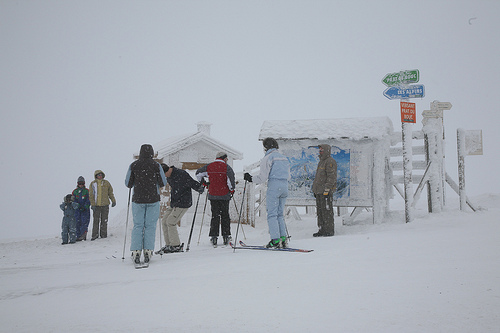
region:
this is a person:
[44, 183, 77, 242]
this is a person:
[61, 172, 101, 248]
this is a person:
[76, 156, 128, 243]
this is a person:
[116, 144, 176, 279]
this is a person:
[153, 152, 200, 269]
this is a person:
[196, 138, 243, 231]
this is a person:
[249, 141, 296, 250]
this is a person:
[306, 137, 358, 254]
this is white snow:
[235, 278, 295, 330]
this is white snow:
[286, 261, 341, 324]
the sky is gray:
[2, 0, 495, 85]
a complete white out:
[1, 2, 498, 327]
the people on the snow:
[88, 129, 378, 276]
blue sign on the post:
[381, 83, 433, 102]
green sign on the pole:
[376, 68, 428, 85]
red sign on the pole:
[398, 97, 418, 127]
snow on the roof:
[143, 118, 255, 148]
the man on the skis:
[228, 130, 346, 260]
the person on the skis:
[106, 141, 175, 277]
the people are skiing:
[110, 133, 362, 270]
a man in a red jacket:
[201, 153, 241, 228]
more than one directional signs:
[368, 64, 431, 147]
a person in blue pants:
[116, 139, 187, 279]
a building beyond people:
[123, 116, 247, 171]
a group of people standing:
[50, 168, 115, 248]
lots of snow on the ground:
[23, 266, 438, 320]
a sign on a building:
[256, 134, 383, 209]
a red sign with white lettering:
[396, 97, 422, 124]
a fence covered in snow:
[391, 127, 472, 220]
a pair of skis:
[226, 237, 320, 269]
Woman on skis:
[230, 231, 318, 257]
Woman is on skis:
[227, 230, 317, 256]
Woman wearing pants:
[263, 177, 290, 239]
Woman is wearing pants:
[262, 183, 295, 243]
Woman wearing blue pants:
[262, 184, 292, 241]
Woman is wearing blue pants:
[262, 185, 287, 241]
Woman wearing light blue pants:
[263, 181, 292, 242]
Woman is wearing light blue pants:
[263, 187, 288, 242]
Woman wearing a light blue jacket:
[257, 146, 294, 186]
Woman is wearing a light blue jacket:
[256, 146, 294, 183]